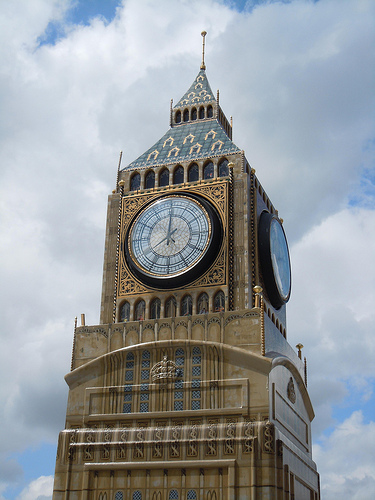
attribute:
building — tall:
[52, 29, 320, 498]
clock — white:
[131, 198, 225, 283]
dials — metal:
[274, 239, 288, 267]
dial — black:
[166, 210, 171, 245]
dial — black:
[149, 219, 179, 249]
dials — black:
[274, 242, 285, 273]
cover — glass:
[267, 215, 294, 300]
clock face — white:
[134, 201, 204, 274]